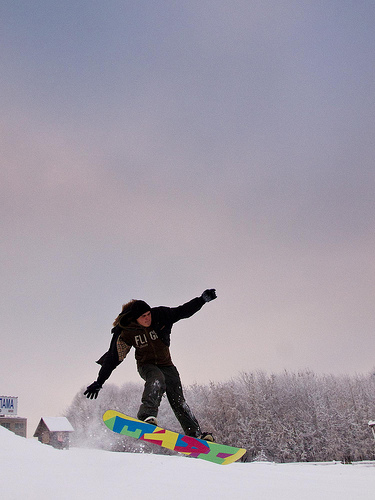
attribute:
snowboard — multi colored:
[70, 387, 256, 492]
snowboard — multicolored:
[98, 406, 246, 469]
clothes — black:
[91, 289, 212, 389]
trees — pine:
[170, 365, 373, 463]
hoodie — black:
[89, 287, 221, 386]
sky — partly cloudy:
[6, 6, 370, 390]